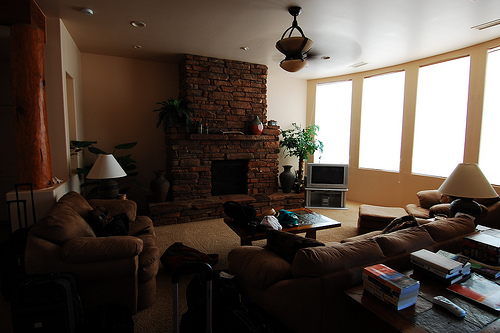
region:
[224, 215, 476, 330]
brown three cushion sofa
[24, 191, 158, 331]
brown two cushion sofa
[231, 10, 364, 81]
ceiling fan running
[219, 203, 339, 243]
wood edged coffee table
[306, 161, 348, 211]
television on tv stand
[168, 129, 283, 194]
stone fireplace on side wall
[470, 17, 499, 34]
air vent in ceiling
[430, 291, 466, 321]
remote control on table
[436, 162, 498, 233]
table lamp with white shade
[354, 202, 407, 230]
tan ottoman in front of chair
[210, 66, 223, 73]
red brick on fireplace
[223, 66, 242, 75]
red brick on fireplace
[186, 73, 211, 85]
red brick on fireplace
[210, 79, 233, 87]
red brick on fireplace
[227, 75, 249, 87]
red brick on fireplace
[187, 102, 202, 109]
red brick on fireplace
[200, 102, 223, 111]
red brick on fireplace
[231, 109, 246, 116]
red brick on fireplace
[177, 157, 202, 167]
red brick on fireplace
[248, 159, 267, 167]
red brick on fireplace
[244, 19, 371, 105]
fan attached to ceiling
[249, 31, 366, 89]
fan blades are running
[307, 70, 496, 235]
cream colored frame on window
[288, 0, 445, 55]
white ceiling near fan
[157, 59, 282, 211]
dark brown brick fireplace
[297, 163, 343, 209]
grey tv near fireplace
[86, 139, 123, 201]
white lampshade behind sofa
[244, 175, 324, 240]
brown table in middle of room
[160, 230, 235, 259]
brown carpet on floor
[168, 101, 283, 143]
numerous objects on fireplace ledge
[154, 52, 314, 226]
fireplace made of stone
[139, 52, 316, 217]
the fireplace is brown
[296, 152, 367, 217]
tv sitting near fireplace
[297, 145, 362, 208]
tv is turned off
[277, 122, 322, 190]
plant behind the tv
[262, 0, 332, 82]
light hanging from ceiling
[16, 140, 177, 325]
lamp beside the couch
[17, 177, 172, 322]
the couch is brown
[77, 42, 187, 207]
the wall is brown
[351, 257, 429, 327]
books on the table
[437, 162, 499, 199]
a white lamp shade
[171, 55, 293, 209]
a rock fire place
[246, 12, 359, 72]
a ceiling fan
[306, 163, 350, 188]
a silver television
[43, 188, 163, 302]
a tan couch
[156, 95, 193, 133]
a plant on the fireplace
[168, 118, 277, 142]
a ledge on the fireplace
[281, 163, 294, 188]
a vase sitting on the fireplace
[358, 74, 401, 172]
a window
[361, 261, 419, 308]
books sitting on a table